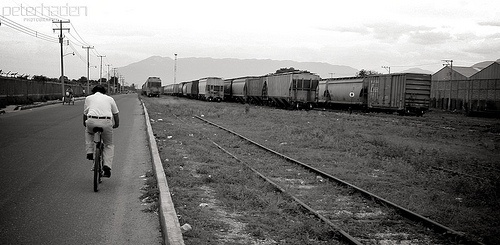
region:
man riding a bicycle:
[62, 74, 134, 202]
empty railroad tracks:
[170, 102, 447, 238]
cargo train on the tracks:
[175, 76, 462, 123]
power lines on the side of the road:
[5, 17, 121, 106]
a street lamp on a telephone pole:
[57, 50, 84, 67]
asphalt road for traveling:
[22, 138, 67, 199]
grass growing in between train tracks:
[297, 108, 471, 195]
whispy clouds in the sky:
[317, 2, 492, 55]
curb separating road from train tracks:
[132, 100, 191, 237]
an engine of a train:
[136, 68, 176, 100]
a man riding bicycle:
[81, 83, 117, 193]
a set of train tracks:
[157, 95, 462, 242]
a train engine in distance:
[146, 76, 160, 96]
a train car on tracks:
[195, 75, 222, 102]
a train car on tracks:
[180, 77, 198, 97]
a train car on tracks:
[175, 80, 184, 94]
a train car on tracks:
[231, 75, 251, 102]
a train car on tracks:
[247, 73, 268, 102]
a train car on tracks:
[265, 65, 317, 107]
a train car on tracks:
[313, 73, 366, 109]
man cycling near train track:
[72, 84, 132, 181]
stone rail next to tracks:
[135, 88, 191, 243]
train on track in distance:
[138, 75, 407, 242]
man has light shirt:
[85, 85, 117, 115]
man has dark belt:
[80, 105, 139, 187]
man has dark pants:
[80, 108, 112, 158]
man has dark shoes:
[92, 145, 124, 177]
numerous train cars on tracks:
[174, 68, 495, 130]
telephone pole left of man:
[42, 6, 77, 93]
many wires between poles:
[7, 9, 113, 77]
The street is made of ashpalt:
[16, 119, 79, 224]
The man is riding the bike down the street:
[78, 78, 125, 195]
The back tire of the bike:
[91, 147, 106, 193]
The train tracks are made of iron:
[191, 115, 424, 242]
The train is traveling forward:
[133, 70, 166, 99]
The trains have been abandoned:
[196, 63, 446, 118]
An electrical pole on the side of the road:
[49, 10, 70, 107]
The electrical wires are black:
[4, 0, 124, 89]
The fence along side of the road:
[5, 68, 86, 104]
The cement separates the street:
[139, 87, 196, 244]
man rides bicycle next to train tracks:
[76, 83, 119, 192]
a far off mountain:
[103, 52, 361, 96]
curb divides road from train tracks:
[129, 88, 187, 243]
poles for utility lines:
[3, 8, 122, 87]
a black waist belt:
[86, 110, 114, 125]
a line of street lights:
[58, 49, 118, 69]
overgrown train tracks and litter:
[151, 90, 478, 243]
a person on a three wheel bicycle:
[60, 83, 80, 109]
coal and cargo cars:
[176, 68, 438, 118]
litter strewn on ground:
[133, 88, 240, 233]